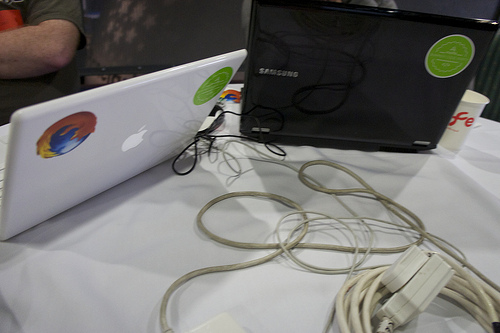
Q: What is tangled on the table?
A: The cords.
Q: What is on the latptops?
A: A sticker.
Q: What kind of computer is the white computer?
A: An apple computer.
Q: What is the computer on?
A: A table.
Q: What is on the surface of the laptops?
A: Stickers.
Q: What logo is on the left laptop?
A: Apple.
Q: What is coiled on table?
A: Wires.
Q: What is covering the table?
A: A tablecloth.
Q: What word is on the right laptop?
A: Samsung.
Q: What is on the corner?
A: A person.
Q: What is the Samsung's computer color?
A: Black.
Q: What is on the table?
A: Laptops.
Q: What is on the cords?
A: Adapter.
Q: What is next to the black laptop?
A: Cup.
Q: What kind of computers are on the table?
A: Laptop computers.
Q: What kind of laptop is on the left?
A: An Apple laptop.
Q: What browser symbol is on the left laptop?
A: Firefox.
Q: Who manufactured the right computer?
A: Samsung.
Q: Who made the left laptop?
A: Apple.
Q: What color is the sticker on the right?
A: Green.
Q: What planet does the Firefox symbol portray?
A: Earth.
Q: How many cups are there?
A: 1.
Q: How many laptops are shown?
A: 2.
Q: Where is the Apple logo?
A: In the middle.